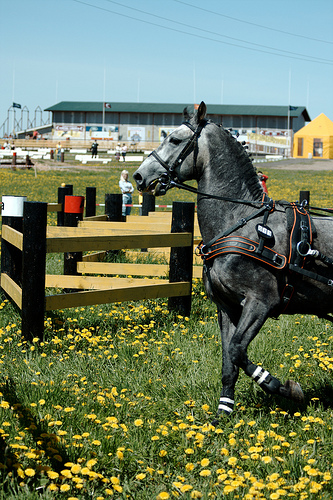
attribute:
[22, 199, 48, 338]
fence post — black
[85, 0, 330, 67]
wires — long